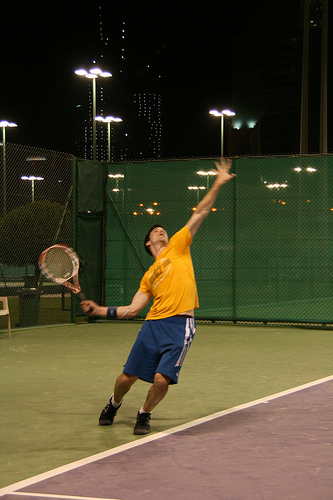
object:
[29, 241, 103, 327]
tennis racquet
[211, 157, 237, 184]
hand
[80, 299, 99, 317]
hand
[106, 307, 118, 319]
arnband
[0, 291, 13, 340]
chair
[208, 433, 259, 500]
ground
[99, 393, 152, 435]
black sneakers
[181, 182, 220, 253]
arm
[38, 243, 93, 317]
racket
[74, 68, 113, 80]
light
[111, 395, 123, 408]
sock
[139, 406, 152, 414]
sock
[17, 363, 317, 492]
white line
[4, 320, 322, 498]
tennis court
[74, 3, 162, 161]
skyscraper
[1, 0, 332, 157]
sky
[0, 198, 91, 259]
bush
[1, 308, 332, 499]
tennis court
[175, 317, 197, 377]
stripes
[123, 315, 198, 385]
shorts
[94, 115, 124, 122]
light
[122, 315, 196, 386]
blue shorts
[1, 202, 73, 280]
tree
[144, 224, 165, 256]
hair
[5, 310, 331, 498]
court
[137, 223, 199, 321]
yellow shirt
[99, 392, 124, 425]
shoe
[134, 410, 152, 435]
shoe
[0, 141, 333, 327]
fence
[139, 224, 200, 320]
shirt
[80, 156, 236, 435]
man